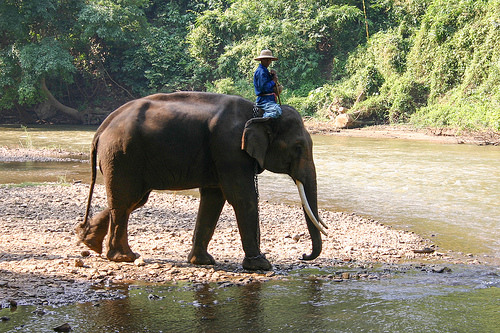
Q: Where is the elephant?
A: By river.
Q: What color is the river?
A: Brown.